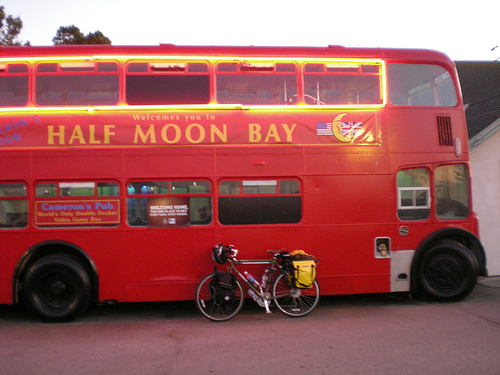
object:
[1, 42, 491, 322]
bus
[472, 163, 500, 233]
wall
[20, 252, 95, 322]
tire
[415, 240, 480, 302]
tire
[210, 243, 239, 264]
helmet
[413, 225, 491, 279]
fender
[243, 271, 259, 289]
water bottle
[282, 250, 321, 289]
bag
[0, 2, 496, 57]
sky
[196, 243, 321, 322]
bike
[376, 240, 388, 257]
spot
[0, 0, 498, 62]
clouds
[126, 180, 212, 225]
window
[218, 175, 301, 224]
window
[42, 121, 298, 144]
words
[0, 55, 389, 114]
light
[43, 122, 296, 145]
writing